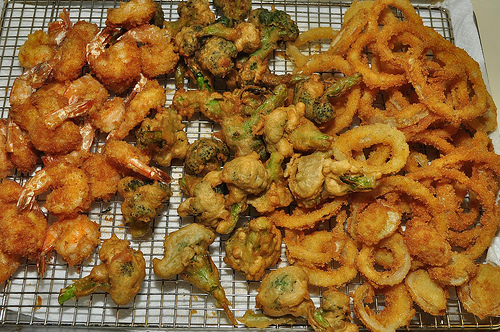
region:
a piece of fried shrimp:
[16, 163, 93, 218]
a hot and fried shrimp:
[16, 168, 91, 219]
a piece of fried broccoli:
[153, 223, 235, 327]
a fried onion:
[404, 38, 492, 127]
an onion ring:
[406, 35, 491, 121]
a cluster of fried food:
[2, 13, 499, 325]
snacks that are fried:
[2, 12, 498, 327]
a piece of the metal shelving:
[142, 284, 196, 324]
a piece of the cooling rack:
[143, 283, 185, 324]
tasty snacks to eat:
[3, 15, 499, 330]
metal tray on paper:
[1, 2, 498, 331]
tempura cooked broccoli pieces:
[60, 0, 378, 327]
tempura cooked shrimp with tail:
[1, 0, 179, 329]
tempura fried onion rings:
[269, 0, 498, 330]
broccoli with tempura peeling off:
[177, 26, 222, 119]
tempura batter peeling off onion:
[351, 282, 413, 331]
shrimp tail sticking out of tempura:
[15, 170, 50, 210]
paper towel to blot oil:
[450, 0, 496, 92]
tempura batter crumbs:
[186, 293, 214, 318]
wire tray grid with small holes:
[134, 292, 219, 325]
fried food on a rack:
[2, 1, 497, 323]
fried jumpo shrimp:
[0, 0, 175, 275]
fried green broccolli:
[57, 2, 357, 327]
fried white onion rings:
[270, 0, 495, 320]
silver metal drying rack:
[0, 1, 498, 326]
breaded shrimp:
[1, 4, 170, 293]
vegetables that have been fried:
[83, 2, 498, 324]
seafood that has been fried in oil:
[1, 1, 173, 283]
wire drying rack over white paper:
[1, 0, 496, 325]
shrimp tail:
[13, 167, 52, 214]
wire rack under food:
[0, 0, 496, 330]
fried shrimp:
[0, 0, 166, 280]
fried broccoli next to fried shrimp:
[0, 0, 370, 330]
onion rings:
[285, 0, 491, 330]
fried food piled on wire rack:
[1, 0, 493, 327]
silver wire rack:
[0, 0, 496, 328]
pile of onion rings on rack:
[281, 1, 494, 328]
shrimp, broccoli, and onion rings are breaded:
[0, 0, 495, 328]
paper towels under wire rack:
[0, 0, 485, 321]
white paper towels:
[1, 1, 497, 326]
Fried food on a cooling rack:
[0, 11, 470, 263]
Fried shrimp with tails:
[11, 11, 167, 214]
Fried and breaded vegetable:
[146, 212, 238, 309]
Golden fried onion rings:
[328, 14, 481, 144]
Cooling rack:
[148, 290, 198, 322]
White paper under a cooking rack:
[6, 7, 192, 313]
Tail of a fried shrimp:
[126, 150, 162, 180]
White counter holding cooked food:
[470, 5, 499, 37]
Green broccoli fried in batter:
[156, 222, 233, 307]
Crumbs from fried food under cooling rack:
[178, 290, 220, 321]